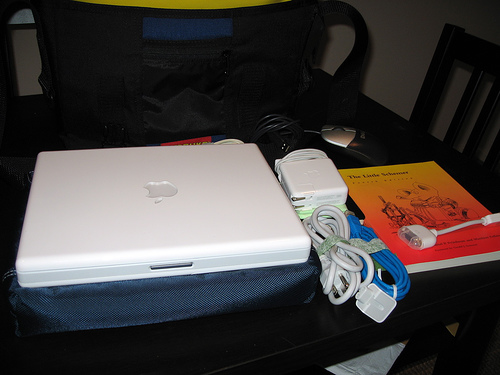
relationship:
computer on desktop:
[15, 143, 311, 292] [24, 95, 455, 321]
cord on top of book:
[395, 209, 499, 249] [334, 159, 499, 272]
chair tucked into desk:
[402, 20, 498, 155] [3, 45, 496, 363]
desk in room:
[3, 45, 496, 363] [0, 10, 496, 372]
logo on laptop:
[140, 172, 185, 207] [10, 131, 332, 338]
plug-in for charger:
[270, 147, 428, 341] [273, 180, 385, 298]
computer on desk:
[15, 143, 311, 292] [3, 45, 496, 363]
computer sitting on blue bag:
[15, 143, 311, 292] [1, 156, 321, 337]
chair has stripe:
[0, 0, 378, 102] [141, 17, 229, 40]